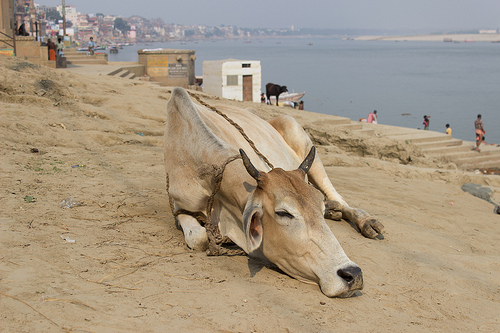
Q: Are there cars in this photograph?
A: No, there are no cars.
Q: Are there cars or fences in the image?
A: No, there are no cars or fences.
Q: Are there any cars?
A: No, there are no cars.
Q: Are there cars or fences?
A: No, there are no cars or fences.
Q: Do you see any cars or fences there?
A: No, there are no cars or fences.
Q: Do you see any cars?
A: No, there are no cars.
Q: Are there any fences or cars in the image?
A: No, there are no cars or fences.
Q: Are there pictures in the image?
A: No, there are no pictures.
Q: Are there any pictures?
A: No, there are no pictures.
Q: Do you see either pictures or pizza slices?
A: No, there are no pictures or pizza slices.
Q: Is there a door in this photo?
A: Yes, there is a door.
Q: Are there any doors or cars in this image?
A: Yes, there is a door.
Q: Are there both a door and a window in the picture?
A: No, there is a door but no windows.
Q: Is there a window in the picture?
A: No, there are no windows.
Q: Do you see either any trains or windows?
A: No, there are no windows or trains.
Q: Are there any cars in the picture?
A: No, there are no cars.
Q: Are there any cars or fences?
A: No, there are no cars or fences.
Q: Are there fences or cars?
A: No, there are no cars or fences.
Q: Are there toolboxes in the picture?
A: No, there are no toolboxes.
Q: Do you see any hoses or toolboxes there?
A: No, there are no toolboxes or hoses.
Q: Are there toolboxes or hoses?
A: No, there are no toolboxes or hoses.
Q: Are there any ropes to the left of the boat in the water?
A: Yes, there is a rope to the left of the boat.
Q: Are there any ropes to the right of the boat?
A: No, the rope is to the left of the boat.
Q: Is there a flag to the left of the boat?
A: No, there is a rope to the left of the boat.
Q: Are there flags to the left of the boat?
A: No, there is a rope to the left of the boat.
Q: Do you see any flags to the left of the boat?
A: No, there is a rope to the left of the boat.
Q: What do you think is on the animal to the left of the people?
A: The rope is on the animal.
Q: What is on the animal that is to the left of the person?
A: The rope is on the animal.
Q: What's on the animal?
A: The rope is on the animal.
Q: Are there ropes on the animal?
A: Yes, there is a rope on the animal.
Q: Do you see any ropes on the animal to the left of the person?
A: Yes, there is a rope on the animal.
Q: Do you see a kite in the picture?
A: No, there are no kites.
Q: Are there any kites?
A: No, there are no kites.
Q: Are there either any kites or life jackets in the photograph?
A: No, there are no kites or life jackets.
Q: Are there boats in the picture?
A: Yes, there is a boat.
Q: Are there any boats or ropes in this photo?
A: Yes, there is a boat.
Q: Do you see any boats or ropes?
A: Yes, there is a boat.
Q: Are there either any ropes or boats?
A: Yes, there is a boat.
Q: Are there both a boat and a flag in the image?
A: No, there is a boat but no flags.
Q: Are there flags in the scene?
A: No, there are no flags.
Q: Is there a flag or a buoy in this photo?
A: No, there are no flags or buoys.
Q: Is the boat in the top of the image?
A: Yes, the boat is in the top of the image.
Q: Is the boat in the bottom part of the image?
A: No, the boat is in the top of the image.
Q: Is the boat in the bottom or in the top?
A: The boat is in the top of the image.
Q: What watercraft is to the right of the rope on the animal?
A: The watercraft is a boat.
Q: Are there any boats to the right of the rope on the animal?
A: Yes, there is a boat to the right of the rope.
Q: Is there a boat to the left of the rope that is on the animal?
A: No, the boat is to the right of the rope.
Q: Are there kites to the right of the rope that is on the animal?
A: No, there is a boat to the right of the rope.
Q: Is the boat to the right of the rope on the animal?
A: Yes, the boat is to the right of the rope.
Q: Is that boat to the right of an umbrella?
A: No, the boat is to the right of the rope.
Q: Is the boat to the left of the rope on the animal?
A: No, the boat is to the right of the rope.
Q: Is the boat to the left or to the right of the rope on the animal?
A: The boat is to the right of the rope.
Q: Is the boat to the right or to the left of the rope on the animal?
A: The boat is to the right of the rope.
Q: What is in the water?
A: The boat is in the water.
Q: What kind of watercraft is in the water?
A: The watercraft is a boat.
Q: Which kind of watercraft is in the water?
A: The watercraft is a boat.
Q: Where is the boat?
A: The boat is in the water.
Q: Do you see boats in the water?
A: Yes, there is a boat in the water.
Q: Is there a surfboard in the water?
A: No, there is a boat in the water.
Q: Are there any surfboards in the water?
A: No, there is a boat in the water.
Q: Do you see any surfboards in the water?
A: No, there is a boat in the water.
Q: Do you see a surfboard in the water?
A: No, there is a boat in the water.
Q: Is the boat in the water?
A: Yes, the boat is in the water.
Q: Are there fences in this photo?
A: No, there are no fences.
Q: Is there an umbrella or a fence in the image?
A: No, there are no fences or umbrellas.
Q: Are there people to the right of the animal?
A: Yes, there are people to the right of the animal.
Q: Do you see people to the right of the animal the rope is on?
A: Yes, there are people to the right of the animal.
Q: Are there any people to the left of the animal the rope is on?
A: No, the people are to the right of the animal.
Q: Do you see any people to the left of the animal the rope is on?
A: No, the people are to the right of the animal.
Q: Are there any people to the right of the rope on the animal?
A: Yes, there are people to the right of the rope.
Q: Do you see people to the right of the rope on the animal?
A: Yes, there are people to the right of the rope.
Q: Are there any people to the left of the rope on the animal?
A: No, the people are to the right of the rope.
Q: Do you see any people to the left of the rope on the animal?
A: No, the people are to the right of the rope.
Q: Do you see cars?
A: No, there are no cars.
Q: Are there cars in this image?
A: No, there are no cars.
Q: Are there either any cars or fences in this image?
A: No, there are no cars or fences.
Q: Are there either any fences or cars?
A: No, there are no cars or fences.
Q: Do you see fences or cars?
A: No, there are no cars or fences.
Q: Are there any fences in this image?
A: No, there are no fences.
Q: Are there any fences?
A: No, there are no fences.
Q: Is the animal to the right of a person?
A: No, the animal is to the left of a person.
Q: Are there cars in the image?
A: No, there are no cars.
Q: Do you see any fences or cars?
A: No, there are no cars or fences.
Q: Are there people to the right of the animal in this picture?
A: Yes, there is a person to the right of the animal.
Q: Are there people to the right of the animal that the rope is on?
A: Yes, there is a person to the right of the animal.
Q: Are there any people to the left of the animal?
A: No, the person is to the right of the animal.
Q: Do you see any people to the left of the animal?
A: No, the person is to the right of the animal.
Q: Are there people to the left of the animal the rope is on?
A: No, the person is to the right of the animal.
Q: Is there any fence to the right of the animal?
A: No, there is a person to the right of the animal.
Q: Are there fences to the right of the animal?
A: No, there is a person to the right of the animal.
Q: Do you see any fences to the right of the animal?
A: No, there is a person to the right of the animal.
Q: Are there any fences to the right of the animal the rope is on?
A: No, there is a person to the right of the animal.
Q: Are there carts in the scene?
A: No, there are no carts.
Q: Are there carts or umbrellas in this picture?
A: No, there are no carts or umbrellas.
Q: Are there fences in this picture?
A: No, there are no fences.